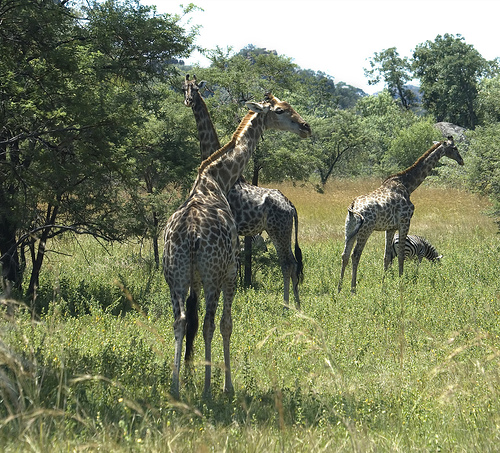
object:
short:
[387, 232, 443, 270]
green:
[414, 275, 486, 318]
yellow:
[270, 338, 320, 362]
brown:
[134, 419, 216, 449]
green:
[71, 31, 157, 113]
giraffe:
[161, 74, 311, 312]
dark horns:
[443, 133, 455, 146]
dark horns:
[262, 90, 289, 105]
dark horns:
[182, 73, 203, 82]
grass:
[5, 228, 498, 448]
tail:
[182, 239, 203, 345]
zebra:
[381, 225, 443, 274]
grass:
[2, 171, 499, 451]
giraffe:
[337, 126, 475, 299]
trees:
[1, 2, 498, 296]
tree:
[0, 0, 106, 321]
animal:
[143, 69, 318, 411]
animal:
[159, 70, 313, 405]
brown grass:
[293, 310, 477, 398]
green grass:
[329, 289, 409, 332]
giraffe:
[131, 73, 468, 408]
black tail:
[180, 295, 202, 378]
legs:
[383, 228, 408, 281]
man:
[384, 138, 442, 183]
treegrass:
[16, 177, 490, 451]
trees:
[41, 2, 155, 309]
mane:
[396, 143, 450, 183]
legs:
[164, 272, 239, 402]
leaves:
[7, 0, 177, 244]